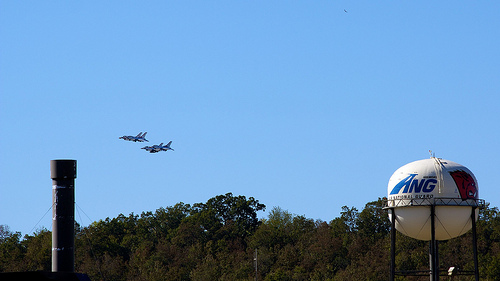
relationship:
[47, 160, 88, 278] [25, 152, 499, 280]
tower in town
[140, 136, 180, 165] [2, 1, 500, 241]
plane in sky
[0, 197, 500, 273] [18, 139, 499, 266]
tree in background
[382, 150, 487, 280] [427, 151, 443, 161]
water tower has point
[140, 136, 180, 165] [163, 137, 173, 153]
plane has tail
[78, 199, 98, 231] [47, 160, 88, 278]
string on tower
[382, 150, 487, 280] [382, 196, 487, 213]
water tower has railing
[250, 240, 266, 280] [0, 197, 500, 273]
pole in tree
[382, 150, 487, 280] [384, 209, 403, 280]
water tower has support pole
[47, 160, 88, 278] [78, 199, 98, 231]
tower has string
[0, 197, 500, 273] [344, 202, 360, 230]
tree has branch